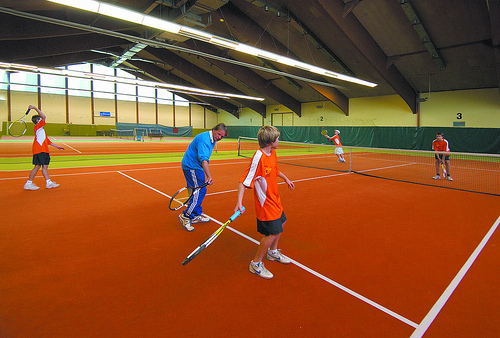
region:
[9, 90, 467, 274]
people playing tennis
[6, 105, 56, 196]
person has tennis racket behind their head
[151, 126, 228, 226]
person in blue outfit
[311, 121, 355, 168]
player is swinging st the ball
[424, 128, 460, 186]
person is slightly bent over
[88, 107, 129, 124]
blue sign on wall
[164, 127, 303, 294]
two people with tennis rackets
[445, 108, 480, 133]
number 3 on the wall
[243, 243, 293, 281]
white tennis shoes with blue nike emblem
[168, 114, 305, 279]
both players are in the swing motion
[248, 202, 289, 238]
THE KID IS WEARING BLACK SHORTS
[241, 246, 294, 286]
THE KID IS WEARING WHITE SHOES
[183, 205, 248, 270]
THE KID IS HOLDING A RACKET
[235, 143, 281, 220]
THE KID IS WEARING AN ORANGE SHIRT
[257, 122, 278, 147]
THE KID HAS BLONDE HAIR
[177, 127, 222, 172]
THE MAN IS WEARING A BLUE SHIRT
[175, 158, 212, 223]
THE MAN IS WEARING BLUE PANTS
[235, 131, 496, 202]
THIS IS A TENNIS NET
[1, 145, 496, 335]
THE COURT IS ORANGE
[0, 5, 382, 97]
THE LIGHTS ARE LONG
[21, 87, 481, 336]
a group of people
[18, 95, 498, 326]
a group of people stanidng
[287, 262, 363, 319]
a white line in the floor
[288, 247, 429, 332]
a white line in the grond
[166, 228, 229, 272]
a bat in the floor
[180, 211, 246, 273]
a tennis bat by boy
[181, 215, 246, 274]
a boy holding bat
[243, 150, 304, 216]
a boy wearing shirt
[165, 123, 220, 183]
a man wearing blue shirt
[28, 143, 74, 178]
a girl wearing shorts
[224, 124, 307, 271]
this is a tennis player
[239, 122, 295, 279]
the player is swinging the racket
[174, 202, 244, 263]
this is the racket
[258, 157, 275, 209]
this is the jersey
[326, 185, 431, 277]
the pitch is red in color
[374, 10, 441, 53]
this is the roof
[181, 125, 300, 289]
A boy swinging a racket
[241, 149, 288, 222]
The boy's orange and white shirt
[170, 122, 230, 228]
A man swinging a racket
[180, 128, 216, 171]
A blue shirt on the man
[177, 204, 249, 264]
A racket with a blue handle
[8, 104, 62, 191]
A boy with his arm over his head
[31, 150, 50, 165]
Black shorts on the boy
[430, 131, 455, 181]
A boy standing by the net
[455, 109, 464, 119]
A black letter on the wall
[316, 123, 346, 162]
A boy swinging at a ball